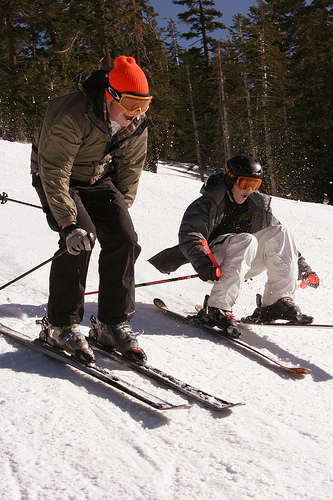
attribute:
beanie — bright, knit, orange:
[105, 56, 149, 98]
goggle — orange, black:
[106, 83, 153, 114]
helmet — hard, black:
[223, 156, 264, 203]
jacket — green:
[31, 71, 150, 226]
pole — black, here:
[1, 232, 95, 291]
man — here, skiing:
[29, 56, 151, 367]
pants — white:
[206, 223, 300, 311]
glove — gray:
[62, 224, 95, 256]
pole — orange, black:
[84, 266, 222, 295]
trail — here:
[1, 139, 331, 500]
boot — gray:
[199, 295, 241, 339]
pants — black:
[32, 180, 143, 328]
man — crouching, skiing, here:
[178, 155, 318, 338]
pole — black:
[1, 194, 45, 210]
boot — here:
[258, 295, 313, 326]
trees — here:
[1, 0, 331, 204]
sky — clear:
[138, 0, 330, 58]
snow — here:
[1, 138, 333, 500]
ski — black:
[1, 321, 190, 411]